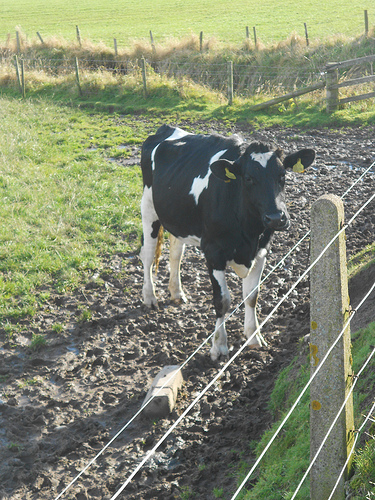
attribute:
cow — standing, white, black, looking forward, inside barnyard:
[136, 122, 316, 361]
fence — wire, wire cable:
[1, 55, 375, 115]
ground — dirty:
[3, 2, 373, 500]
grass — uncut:
[3, 4, 374, 335]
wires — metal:
[15, 55, 374, 88]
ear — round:
[211, 156, 241, 182]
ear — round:
[282, 147, 316, 175]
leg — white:
[245, 252, 266, 353]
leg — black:
[203, 243, 236, 360]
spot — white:
[249, 151, 277, 167]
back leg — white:
[137, 182, 160, 307]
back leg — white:
[167, 230, 185, 305]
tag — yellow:
[222, 167, 242, 184]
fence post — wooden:
[139, 57, 154, 99]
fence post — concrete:
[306, 193, 359, 499]